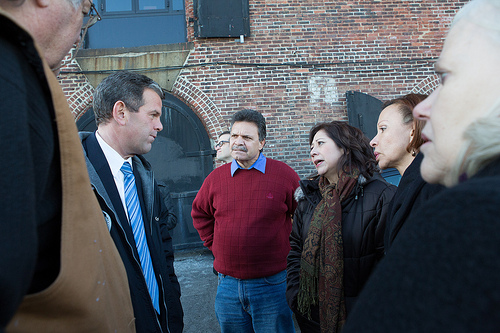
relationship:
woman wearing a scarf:
[288, 122, 399, 332] [299, 175, 367, 332]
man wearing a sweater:
[193, 110, 291, 332] [190, 160, 300, 278]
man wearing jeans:
[193, 110, 291, 332] [216, 272, 298, 333]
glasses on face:
[79, 1, 101, 29] [46, 2, 100, 74]